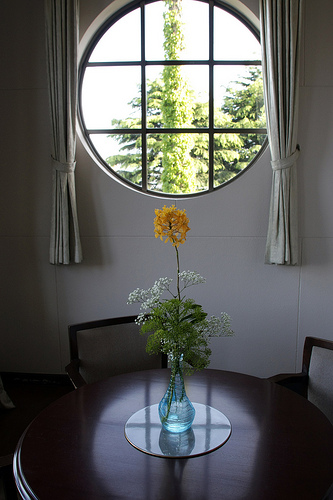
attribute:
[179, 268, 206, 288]
babys breath — white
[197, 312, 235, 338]
babys breath — white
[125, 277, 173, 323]
babys breath — white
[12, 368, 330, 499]
table — round, dark, brown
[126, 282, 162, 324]
baby's breath — white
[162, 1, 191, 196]
tree — tall, green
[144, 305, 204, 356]
plant — green, filler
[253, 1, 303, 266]
curtain — grey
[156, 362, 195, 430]
vase — white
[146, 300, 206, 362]
filler — green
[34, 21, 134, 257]
curtain — grey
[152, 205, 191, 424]
flower — tall, yellow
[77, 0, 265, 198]
window — round paned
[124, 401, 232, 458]
mirror plate — round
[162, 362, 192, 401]
vase — clear, blue, flower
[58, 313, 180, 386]
chair — dark, wood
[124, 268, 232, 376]
baby's breath — white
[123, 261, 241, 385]
baby's breath — white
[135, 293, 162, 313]
baby's breath — white